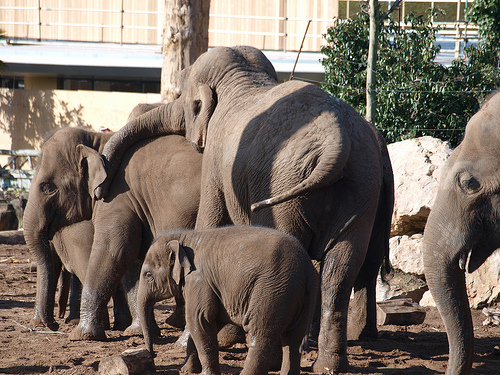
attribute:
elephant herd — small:
[21, 46, 498, 373]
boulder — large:
[385, 137, 453, 237]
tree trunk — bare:
[162, 0, 207, 102]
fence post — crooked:
[367, 1, 376, 122]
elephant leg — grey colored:
[282, 310, 303, 372]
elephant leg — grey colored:
[182, 289, 222, 369]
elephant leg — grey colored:
[309, 237, 368, 373]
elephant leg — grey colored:
[68, 206, 141, 344]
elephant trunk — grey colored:
[419, 189, 476, 372]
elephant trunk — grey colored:
[136, 287, 158, 357]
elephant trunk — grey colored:
[91, 94, 181, 200]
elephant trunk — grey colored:
[21, 202, 63, 332]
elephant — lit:
[94, 44, 381, 373]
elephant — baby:
[133, 227, 319, 372]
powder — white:
[76, 286, 98, 332]